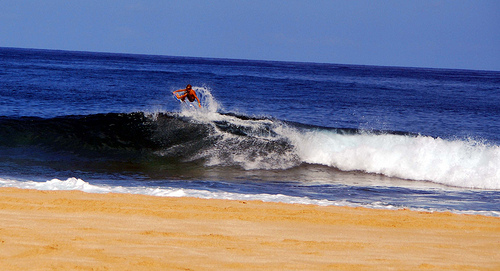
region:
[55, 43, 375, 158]
a body of water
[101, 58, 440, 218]
a body of blue water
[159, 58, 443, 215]
a body of water that is blue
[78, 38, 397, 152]
a body of water with waves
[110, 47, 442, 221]
a large water wavve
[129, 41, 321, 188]
a man that is surfing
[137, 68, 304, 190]
a man surfing the wave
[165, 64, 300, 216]
a man riding the wave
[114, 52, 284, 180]
a man on a surfboard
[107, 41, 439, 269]
a man that is surfing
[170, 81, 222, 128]
A person surfing a wave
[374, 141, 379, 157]
part of a wave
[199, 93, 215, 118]
part of a board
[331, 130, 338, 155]
part of a lake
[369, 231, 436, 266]
Tan sandy beach near water.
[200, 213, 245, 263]
Tan sandy beach near water.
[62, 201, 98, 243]
Tan sandy beach near water.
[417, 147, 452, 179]
Top of wave is white.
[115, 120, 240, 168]
Large wave rolling on to short.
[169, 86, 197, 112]
Man standing on top of surfboard.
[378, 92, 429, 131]
Blue water in ocean.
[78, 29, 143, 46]
Sky is blue and clear.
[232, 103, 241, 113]
part of a board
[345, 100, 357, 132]
part of the ocean